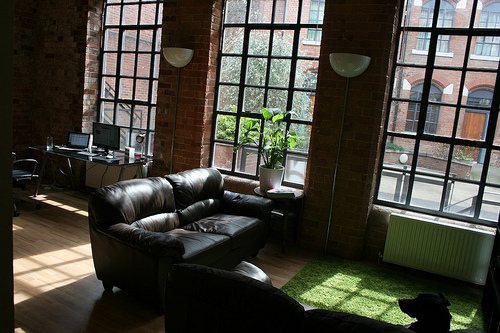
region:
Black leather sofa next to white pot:
[90, 160, 282, 305]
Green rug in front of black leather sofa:
[277, 245, 484, 331]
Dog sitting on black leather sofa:
[388, 281, 455, 331]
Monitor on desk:
[87, 120, 124, 156]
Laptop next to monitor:
[60, 132, 90, 151]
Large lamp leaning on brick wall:
[316, 45, 371, 254]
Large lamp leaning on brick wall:
[155, 42, 197, 179]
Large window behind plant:
[205, 0, 326, 192]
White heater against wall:
[375, 207, 496, 289]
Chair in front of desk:
[12, 144, 42, 226]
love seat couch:
[81, 126, 319, 331]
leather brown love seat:
[72, 162, 269, 277]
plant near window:
[230, 111, 312, 208]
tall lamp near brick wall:
[326, 39, 376, 303]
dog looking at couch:
[380, 284, 468, 329]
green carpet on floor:
[308, 247, 405, 331]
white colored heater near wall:
[372, 210, 494, 285]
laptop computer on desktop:
[50, 126, 91, 161]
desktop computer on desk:
[85, 115, 140, 180]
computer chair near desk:
[0, 127, 42, 239]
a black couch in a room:
[79, 159, 284, 291]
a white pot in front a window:
[240, 102, 300, 197]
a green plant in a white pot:
[244, 101, 302, 193]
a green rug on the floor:
[281, 250, 482, 331]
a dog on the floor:
[385, 284, 464, 331]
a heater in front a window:
[376, 205, 496, 287]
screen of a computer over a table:
[86, 111, 127, 158]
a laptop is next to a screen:
[56, 127, 94, 153]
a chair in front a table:
[11, 144, 46, 206]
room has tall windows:
[99, 0, 491, 220]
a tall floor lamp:
[319, 45, 371, 258]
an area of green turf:
[282, 259, 484, 331]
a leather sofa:
[81, 157, 282, 299]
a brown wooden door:
[464, 113, 485, 157]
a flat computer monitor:
[90, 117, 122, 154]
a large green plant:
[232, 102, 303, 188]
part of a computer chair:
[15, 148, 43, 203]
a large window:
[373, 0, 496, 223]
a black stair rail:
[105, 81, 143, 146]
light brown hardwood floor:
[13, 185, 307, 330]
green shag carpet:
[285, 237, 398, 332]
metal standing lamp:
[308, 18, 378, 276]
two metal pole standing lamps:
[135, 43, 385, 217]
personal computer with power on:
[58, 114, 128, 165]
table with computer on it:
[23, 113, 145, 212]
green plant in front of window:
[230, 99, 308, 198]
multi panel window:
[207, 3, 331, 203]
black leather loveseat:
[86, 163, 278, 299]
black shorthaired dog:
[394, 283, 457, 331]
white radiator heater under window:
[376, 204, 498, 294]